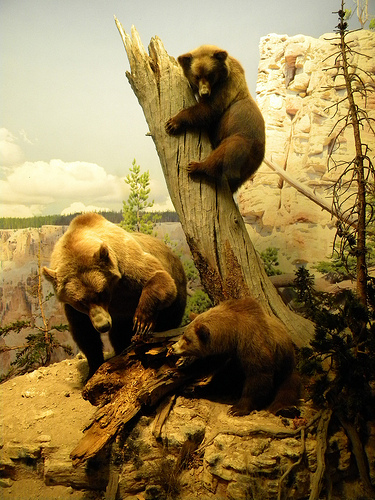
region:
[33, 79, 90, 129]
the sky is clear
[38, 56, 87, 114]
the sky is clear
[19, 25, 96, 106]
the sky is clear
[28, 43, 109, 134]
the sky is clear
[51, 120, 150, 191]
the sky is clear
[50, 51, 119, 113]
the sky is clear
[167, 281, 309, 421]
the bear is black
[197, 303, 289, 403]
the bear is black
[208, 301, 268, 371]
the bear is black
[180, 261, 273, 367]
the bear is black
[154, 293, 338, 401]
the bear is lying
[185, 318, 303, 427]
the bear is lying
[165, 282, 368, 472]
the bear is lying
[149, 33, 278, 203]
the bear is hanging on the side of the tree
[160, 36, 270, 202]
the bear is redish brown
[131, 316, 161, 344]
the bears claws are black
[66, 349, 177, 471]
the bears use the wood to sharpen their claws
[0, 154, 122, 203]
the cloud is white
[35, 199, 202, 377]
the bear is on a cliff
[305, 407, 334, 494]
the tree roots are brown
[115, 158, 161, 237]
the tree in the background is green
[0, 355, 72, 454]
the ledge is very rocky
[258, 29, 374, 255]
the ledge is white rock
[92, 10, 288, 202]
Young brown bear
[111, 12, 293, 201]
Brown bear climbing tree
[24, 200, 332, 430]
Two brown bears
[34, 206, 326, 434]
Two stuffed brown bears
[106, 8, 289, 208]
Young stuffed brown bear on top of tree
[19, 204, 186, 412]
Large brown bear looking for food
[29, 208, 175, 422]
Stuffed brown bear looking for grubs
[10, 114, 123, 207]
White clouds in blue sky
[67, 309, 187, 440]
Fallen split log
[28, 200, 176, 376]
Large brown bear with sharp claws